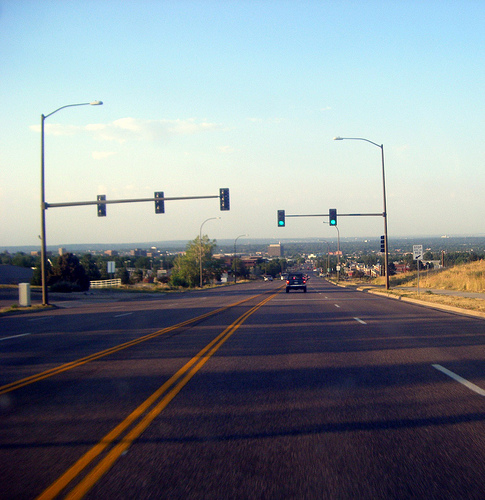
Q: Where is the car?
A: ON the road.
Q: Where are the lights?
A: On the poles.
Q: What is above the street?
A: Traffic lights.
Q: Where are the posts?
A: On the side of the road.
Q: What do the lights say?
A: Go.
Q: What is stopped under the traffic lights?
A: A vehicle.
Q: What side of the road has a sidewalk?
A: The right.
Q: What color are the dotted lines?
A: White.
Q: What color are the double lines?
A: Yellow.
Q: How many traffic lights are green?
A: Two.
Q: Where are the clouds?
A: In the sky.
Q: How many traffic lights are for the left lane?
A: Three.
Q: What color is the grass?
A: Yellow.